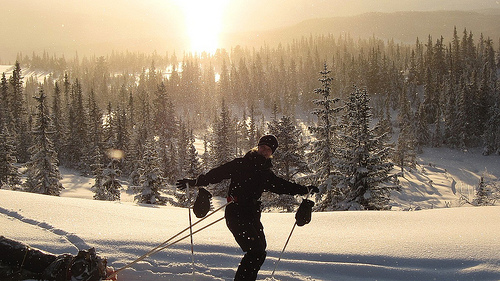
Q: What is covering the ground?
A: Snow.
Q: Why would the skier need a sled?
A: To transport.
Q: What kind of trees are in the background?
A: Pine Trees.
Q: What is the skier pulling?
A: A sled.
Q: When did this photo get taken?
A: At sunrise or sunset.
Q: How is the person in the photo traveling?
A: By skis.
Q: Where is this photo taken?
A: The mountain.